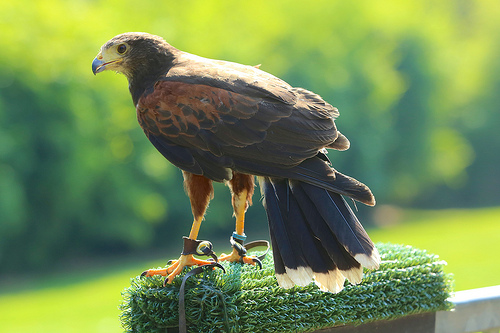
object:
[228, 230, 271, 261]
strap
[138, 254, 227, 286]
feet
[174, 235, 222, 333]
tether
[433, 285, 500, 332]
railing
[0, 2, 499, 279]
trees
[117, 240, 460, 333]
mat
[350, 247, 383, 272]
tips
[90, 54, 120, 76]
beak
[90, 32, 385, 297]
bird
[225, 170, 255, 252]
leg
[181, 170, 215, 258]
leg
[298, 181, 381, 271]
feather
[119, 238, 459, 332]
perch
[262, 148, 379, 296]
tail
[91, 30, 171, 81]
head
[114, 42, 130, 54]
eye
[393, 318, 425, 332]
wood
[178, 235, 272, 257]
cups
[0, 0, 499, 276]
bushes